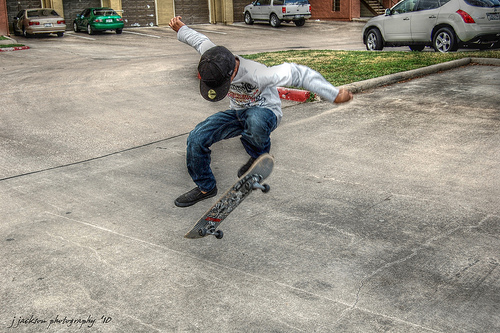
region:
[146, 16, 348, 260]
a boy performing a skateboard trick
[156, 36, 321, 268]
a boy jumping in the air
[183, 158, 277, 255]
a grey skateboard in midair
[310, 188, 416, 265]
grey concrete surface of the road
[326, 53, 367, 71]
green grass growing in the courtyard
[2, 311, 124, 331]
the name of the photographer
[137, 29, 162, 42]
white lines painted on the parking lot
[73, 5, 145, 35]
a gren car parked next to a building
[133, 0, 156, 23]
brown garage door of the building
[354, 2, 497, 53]
a white SUV parked in the lot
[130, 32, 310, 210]
this is a boy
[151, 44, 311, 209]
the boy is skating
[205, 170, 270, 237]
this is a skate board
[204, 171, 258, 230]
the board is tilted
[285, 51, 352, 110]
this is the hand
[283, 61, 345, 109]
the hand is bent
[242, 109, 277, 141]
the knee is bent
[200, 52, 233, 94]
this is a snap back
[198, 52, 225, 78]
the cap is black in color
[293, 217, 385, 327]
this is the floor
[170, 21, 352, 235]
A young child on a skateboard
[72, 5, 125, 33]
A parked green car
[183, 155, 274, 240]
A small skateboard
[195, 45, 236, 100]
A black baseball cap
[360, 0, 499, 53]
A parked white compact car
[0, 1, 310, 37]
Several vehicles parked by a building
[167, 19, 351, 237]
A young child popping a wheelie with a skateboard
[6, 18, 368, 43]
Designated parking area in front of a building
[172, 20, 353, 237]
A young child using a skateboard in a open lot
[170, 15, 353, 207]
A young boy wearing a black baseball hat, white shirt, and bluejeans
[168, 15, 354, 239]
Young boy performing trick on skateboard.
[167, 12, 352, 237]
A skateboarder doing a trick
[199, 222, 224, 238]
The truck on a skateboard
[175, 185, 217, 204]
A skate shoe worn on right foot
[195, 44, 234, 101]
A black hat being worn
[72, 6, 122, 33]
A green motor vehicle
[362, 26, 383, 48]
Left front tire of a car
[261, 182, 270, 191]
Wheel on a skateboard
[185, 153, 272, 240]
A cool gray skateboard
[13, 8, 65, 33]
A tan colored car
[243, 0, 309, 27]
An SUV that is parked